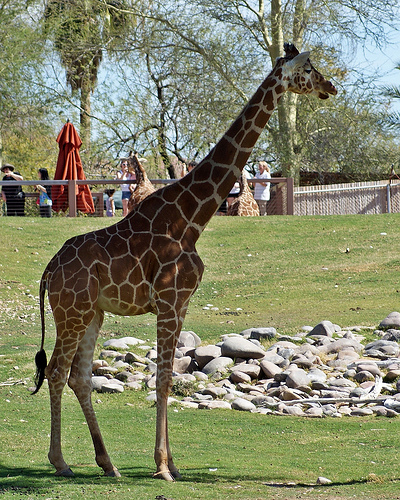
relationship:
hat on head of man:
[0, 156, 16, 174] [0, 164, 29, 214]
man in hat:
[0, 159, 28, 219] [0, 162, 16, 174]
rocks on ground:
[196, 317, 343, 395] [241, 231, 351, 301]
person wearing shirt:
[250, 157, 275, 210] [252, 171, 270, 200]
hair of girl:
[37, 160, 61, 182] [29, 159, 59, 216]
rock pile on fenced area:
[91, 309, 399, 418] [1, 175, 399, 497]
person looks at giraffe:
[251, 161, 271, 215] [31, 42, 337, 483]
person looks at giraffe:
[110, 148, 139, 214] [31, 42, 337, 483]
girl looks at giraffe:
[34, 168, 54, 217] [31, 42, 337, 483]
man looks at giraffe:
[0, 163, 26, 215] [31, 42, 337, 483]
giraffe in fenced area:
[40, 47, 338, 488] [1, 175, 399, 497]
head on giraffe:
[266, 39, 341, 87] [67, 65, 297, 381]